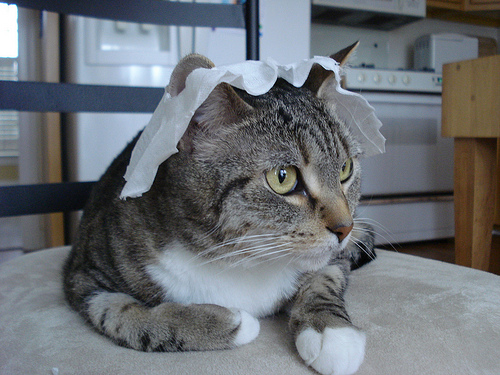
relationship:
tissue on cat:
[253, 51, 307, 93] [122, 101, 411, 357]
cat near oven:
[122, 101, 411, 357] [359, 65, 459, 182]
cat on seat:
[122, 101, 411, 357] [378, 267, 474, 339]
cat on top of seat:
[122, 101, 411, 357] [378, 267, 474, 339]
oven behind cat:
[359, 65, 459, 182] [122, 101, 411, 357]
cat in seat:
[122, 101, 411, 357] [378, 267, 474, 339]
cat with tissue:
[122, 101, 411, 357] [253, 51, 307, 93]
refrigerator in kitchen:
[69, 5, 247, 178] [1, 3, 478, 230]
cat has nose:
[122, 101, 411, 357] [325, 212, 357, 244]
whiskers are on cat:
[193, 227, 296, 274] [122, 101, 411, 357]